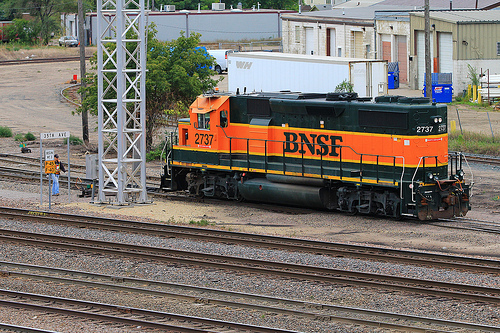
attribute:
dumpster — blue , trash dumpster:
[423, 72, 460, 105]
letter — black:
[275, 132, 359, 159]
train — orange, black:
[185, 81, 435, 216]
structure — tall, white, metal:
[93, 0, 153, 207]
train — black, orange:
[180, 85, 460, 214]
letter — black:
[314, 120, 329, 159]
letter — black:
[328, 125, 353, 168]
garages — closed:
[278, 8, 478, 103]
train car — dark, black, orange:
[166, 88, 475, 220]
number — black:
[194, 132, 214, 146]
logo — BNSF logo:
[281, 125, 343, 159]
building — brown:
[414, 17, 499, 59]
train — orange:
[160, 68, 455, 203]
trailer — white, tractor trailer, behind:
[224, 50, 389, 97]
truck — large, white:
[224, 50, 387, 100]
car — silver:
[162, 89, 489, 254]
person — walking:
[45, 151, 68, 198]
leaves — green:
[159, 57, 167, 64]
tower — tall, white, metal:
[92, 0, 153, 207]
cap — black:
[52, 152, 60, 159]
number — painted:
[194, 132, 213, 145]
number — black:
[178, 124, 206, 146]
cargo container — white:
[223, 48, 388, 100]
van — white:
[185, 29, 266, 81]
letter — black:
[297, 130, 319, 157]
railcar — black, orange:
[166, 92, 472, 217]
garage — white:
[411, 27, 453, 96]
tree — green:
[91, 27, 211, 133]